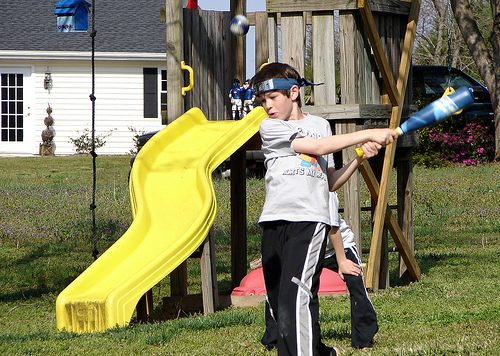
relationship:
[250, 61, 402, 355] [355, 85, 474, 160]
boy swinging bat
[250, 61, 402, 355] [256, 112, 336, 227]
boy wearing shirt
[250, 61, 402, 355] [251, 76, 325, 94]
boy wearing headband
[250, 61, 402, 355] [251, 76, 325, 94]
boy with bandana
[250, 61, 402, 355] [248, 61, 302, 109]
boy has dark hair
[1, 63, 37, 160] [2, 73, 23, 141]
door has windows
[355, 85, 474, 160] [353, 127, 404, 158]
bat has yellow handle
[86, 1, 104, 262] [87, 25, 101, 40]
rope has knot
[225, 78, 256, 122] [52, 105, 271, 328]
toys on slide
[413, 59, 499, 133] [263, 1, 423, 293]
vehicle behind playhouse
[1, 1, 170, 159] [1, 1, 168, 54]
house has rooftop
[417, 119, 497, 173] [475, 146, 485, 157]
bush has flower